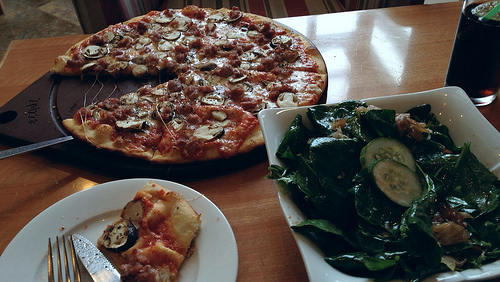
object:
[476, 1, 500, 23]
straw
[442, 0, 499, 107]
glass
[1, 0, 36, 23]
tiles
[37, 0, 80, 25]
tile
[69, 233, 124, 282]
knife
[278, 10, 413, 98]
light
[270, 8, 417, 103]
reflection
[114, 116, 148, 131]
mushrooms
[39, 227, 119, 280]
white plates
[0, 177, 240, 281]
dish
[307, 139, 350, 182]
spinach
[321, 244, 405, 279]
salad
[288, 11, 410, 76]
table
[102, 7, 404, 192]
food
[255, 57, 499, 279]
bowl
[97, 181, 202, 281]
pizza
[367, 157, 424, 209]
cucumber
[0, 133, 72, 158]
utensil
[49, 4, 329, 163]
pizza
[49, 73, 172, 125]
pan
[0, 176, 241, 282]
plate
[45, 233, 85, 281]
fork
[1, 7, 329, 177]
plate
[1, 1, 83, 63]
floor